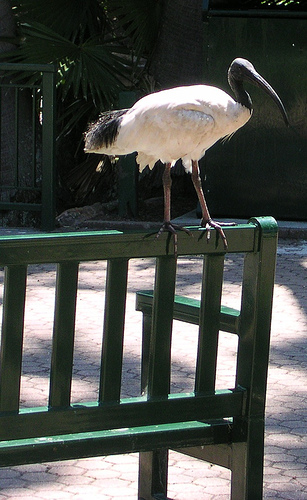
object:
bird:
[83, 55, 290, 259]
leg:
[189, 158, 215, 224]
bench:
[0, 215, 279, 499]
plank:
[195, 251, 225, 399]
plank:
[144, 256, 177, 401]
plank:
[97, 258, 129, 407]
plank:
[46, 264, 79, 411]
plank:
[0, 266, 29, 414]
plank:
[133, 286, 241, 334]